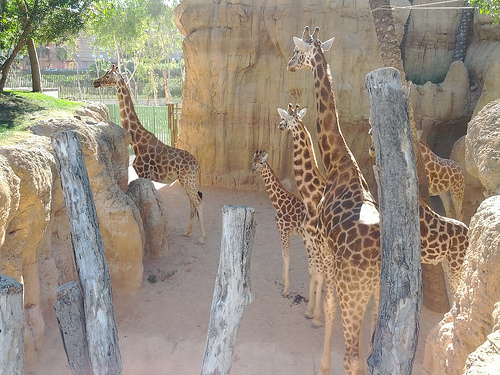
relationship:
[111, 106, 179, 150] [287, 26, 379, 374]
fence behind giraffe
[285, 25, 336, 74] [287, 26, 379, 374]
head of giraffe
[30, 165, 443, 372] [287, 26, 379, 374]
ground under giraffe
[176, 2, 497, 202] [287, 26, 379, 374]
wall near giraffe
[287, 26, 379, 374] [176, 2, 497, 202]
giraffe by wall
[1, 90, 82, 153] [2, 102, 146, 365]
grass on top of cliff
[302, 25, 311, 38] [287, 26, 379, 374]
horn on giraffe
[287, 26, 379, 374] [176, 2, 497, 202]
giraffe next to wall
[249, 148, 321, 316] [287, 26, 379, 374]
baby next to giraffe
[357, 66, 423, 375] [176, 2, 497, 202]
stump by wall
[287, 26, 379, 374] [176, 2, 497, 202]
giraffe near wall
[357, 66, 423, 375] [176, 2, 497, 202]
stump near wall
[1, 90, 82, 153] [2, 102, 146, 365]
grass near cliff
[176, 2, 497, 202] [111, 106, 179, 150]
wall near fence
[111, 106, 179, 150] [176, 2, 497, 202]
fence near wall